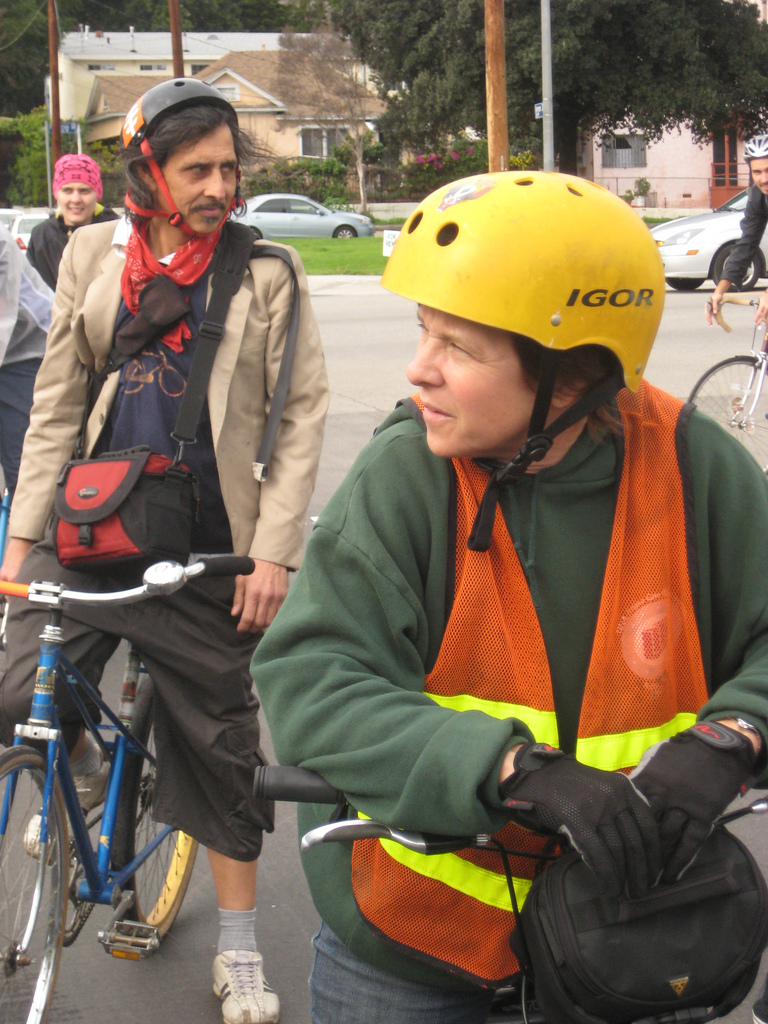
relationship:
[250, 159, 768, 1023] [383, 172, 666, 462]
man has head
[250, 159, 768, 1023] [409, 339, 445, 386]
man has nose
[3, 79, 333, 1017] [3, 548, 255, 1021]
man sitting on bicycle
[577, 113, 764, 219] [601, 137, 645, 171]
house has window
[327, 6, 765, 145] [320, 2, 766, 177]
leaves on tree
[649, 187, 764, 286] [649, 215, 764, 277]
car has front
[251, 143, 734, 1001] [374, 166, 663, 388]
man wearing helmet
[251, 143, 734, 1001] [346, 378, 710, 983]
man wearing safety vest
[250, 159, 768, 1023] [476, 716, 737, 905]
man wearing gloves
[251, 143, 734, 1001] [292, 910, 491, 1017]
man wearing jeans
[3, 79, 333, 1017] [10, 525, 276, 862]
man wearing shorts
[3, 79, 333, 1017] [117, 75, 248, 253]
man wearing helmet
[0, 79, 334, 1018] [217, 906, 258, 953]
man wearing socks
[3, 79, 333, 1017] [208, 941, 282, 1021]
man wearing shoe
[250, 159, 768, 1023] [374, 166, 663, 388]
man wearing helmet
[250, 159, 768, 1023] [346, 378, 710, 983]
man wearing safety vest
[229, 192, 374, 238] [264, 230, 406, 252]
vehicle near a curbside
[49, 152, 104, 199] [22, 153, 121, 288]
hat on a woman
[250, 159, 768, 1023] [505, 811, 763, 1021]
man holding bag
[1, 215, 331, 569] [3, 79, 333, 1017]
suit jacket on a man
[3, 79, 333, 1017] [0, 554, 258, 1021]
man on a bicycle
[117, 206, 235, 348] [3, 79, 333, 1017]
scarf on a man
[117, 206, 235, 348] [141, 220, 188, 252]
scarf on a neck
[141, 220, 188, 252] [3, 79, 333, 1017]
neck of a man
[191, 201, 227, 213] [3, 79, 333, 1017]
mustache on a man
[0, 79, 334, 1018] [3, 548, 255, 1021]
man on a bicycle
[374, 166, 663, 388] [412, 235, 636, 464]
helmet on a head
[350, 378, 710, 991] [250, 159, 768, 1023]
safety vest on a man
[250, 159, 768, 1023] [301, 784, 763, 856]
man leaning on handlebars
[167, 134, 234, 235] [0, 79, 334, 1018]
face on a man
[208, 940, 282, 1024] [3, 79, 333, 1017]
shoe on a man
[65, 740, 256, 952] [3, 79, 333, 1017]
socks on a man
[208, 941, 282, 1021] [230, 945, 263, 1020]
shoe has lace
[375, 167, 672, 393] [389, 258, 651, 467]
helmet on head